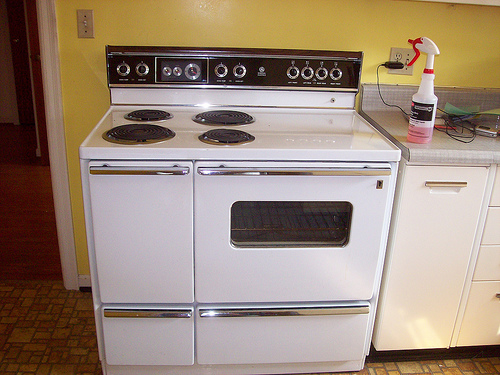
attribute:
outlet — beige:
[385, 49, 423, 77]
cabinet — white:
[375, 164, 494, 344]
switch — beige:
[76, 10, 95, 38]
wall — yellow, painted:
[56, 2, 486, 94]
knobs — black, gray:
[114, 57, 347, 84]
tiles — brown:
[361, 354, 500, 375]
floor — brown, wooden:
[6, 166, 62, 280]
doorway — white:
[35, 1, 84, 292]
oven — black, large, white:
[91, 154, 395, 302]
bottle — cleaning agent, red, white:
[406, 35, 446, 141]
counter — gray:
[366, 86, 499, 169]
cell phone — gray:
[468, 118, 499, 147]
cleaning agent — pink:
[407, 125, 441, 147]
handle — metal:
[198, 156, 395, 186]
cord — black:
[376, 62, 420, 131]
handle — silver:
[90, 155, 192, 181]